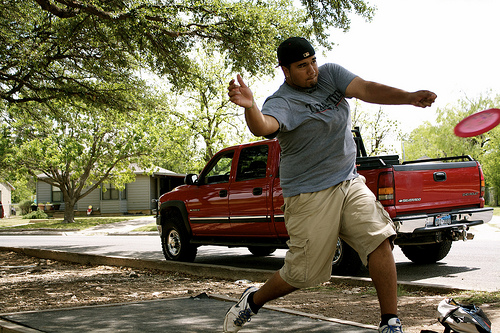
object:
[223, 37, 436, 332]
man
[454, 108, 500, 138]
frisbee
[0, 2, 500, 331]
air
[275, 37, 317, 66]
cap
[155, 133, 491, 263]
truck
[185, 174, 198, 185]
mirror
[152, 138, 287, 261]
side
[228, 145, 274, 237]
door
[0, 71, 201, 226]
tree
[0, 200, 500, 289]
street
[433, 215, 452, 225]
plate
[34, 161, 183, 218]
house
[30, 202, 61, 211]
row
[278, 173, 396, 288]
shorts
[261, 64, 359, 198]
shirt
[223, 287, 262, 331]
sneaker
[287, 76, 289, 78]
earring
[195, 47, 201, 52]
leaf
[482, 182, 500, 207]
house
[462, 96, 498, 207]
tree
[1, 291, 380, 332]
sidewalk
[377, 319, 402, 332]
shoe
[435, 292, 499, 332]
pack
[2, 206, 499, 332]
ground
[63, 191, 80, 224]
trunk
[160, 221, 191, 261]
tire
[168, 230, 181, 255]
rim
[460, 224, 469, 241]
hitch